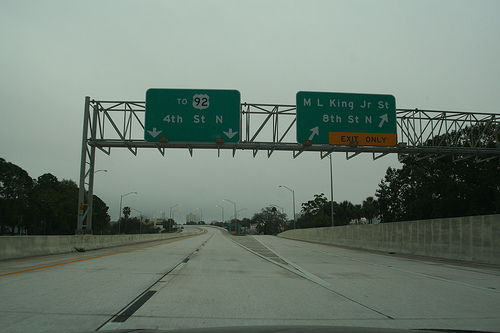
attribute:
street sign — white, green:
[293, 88, 405, 155]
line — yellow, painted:
[55, 236, 200, 258]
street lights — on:
[93, 148, 338, 225]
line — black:
[107, 284, 160, 329]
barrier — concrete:
[290, 203, 495, 280]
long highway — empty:
[0, 216, 493, 330]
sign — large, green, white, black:
[291, 84, 403, 156]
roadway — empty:
[63, 177, 478, 324]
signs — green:
[143, 87, 398, 149]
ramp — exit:
[192, 218, 220, 235]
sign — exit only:
[298, 87, 397, 148]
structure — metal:
[77, 83, 497, 238]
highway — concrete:
[120, 172, 492, 312]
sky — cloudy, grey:
[1, 1, 490, 231]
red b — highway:
[133, 82, 408, 151]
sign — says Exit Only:
[325, 130, 402, 151]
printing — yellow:
[167, 96, 393, 144]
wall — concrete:
[265, 220, 483, 264]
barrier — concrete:
[11, 234, 89, 259]